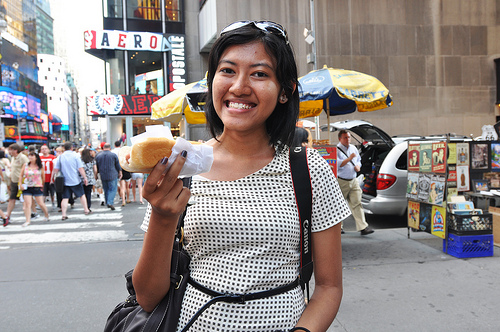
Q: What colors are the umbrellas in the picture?
A: Blue and Yellow.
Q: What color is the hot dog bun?
A: Light brown.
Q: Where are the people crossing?
A: At the crosswalk.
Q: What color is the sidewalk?
A: Gray.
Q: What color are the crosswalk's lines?
A: White.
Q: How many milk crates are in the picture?
A: Two.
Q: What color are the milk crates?
A: Black and Blue.